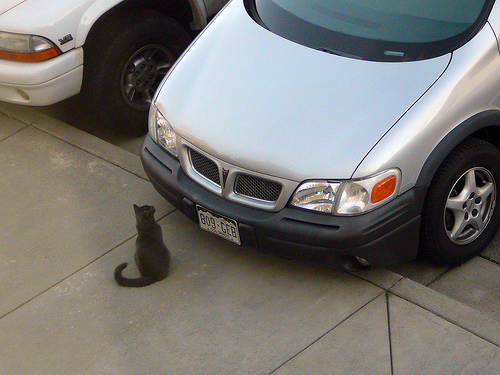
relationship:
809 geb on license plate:
[192, 208, 241, 246] [187, 198, 252, 263]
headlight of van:
[287, 185, 354, 217] [144, 2, 496, 284]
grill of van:
[176, 153, 296, 225] [144, 2, 496, 284]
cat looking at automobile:
[110, 197, 187, 298] [138, 0, 498, 279]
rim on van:
[444, 167, 499, 245] [144, 2, 496, 284]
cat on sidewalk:
[110, 203, 174, 288] [3, 117, 491, 368]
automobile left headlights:
[138, 4, 498, 258] [299, 174, 404, 213]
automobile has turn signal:
[138, 0, 498, 279] [368, 172, 398, 202]